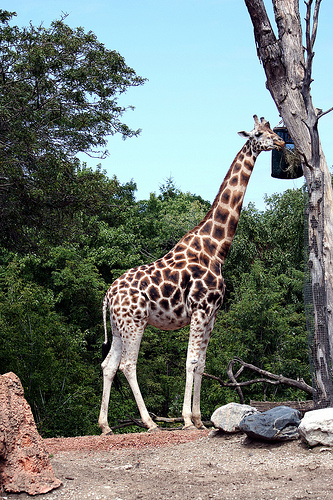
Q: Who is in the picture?
A: A giraffe.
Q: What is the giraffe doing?
A: Eating.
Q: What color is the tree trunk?
A: Brown.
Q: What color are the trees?
A: Green.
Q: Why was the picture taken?
A: To capture the giraffe.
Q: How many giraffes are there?
A: 1.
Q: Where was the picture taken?
A: In a zoo.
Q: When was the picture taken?
A: In the day time.